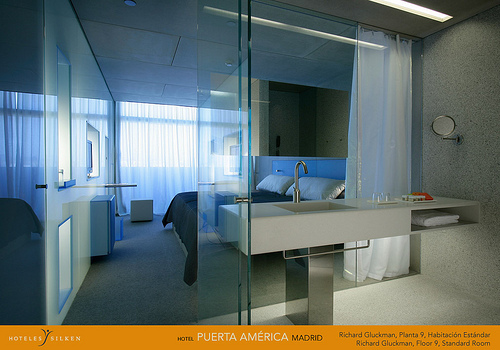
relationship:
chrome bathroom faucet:
[278, 151, 322, 218] [256, 159, 341, 262]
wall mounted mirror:
[447, 50, 480, 78] [418, 87, 482, 179]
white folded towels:
[417, 201, 478, 249] [431, 199, 465, 228]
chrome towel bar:
[278, 151, 322, 218] [266, 235, 374, 273]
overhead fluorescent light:
[376, 11, 465, 47] [375, 7, 460, 31]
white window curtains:
[417, 201, 478, 249] [106, 94, 178, 174]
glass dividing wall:
[208, 16, 261, 70] [447, 50, 480, 78]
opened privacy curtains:
[246, 26, 399, 230] [106, 94, 178, 174]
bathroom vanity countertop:
[273, 205, 374, 266] [369, 200, 392, 214]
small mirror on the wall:
[422, 112, 470, 126] [452, 109, 475, 179]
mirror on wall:
[418, 87, 482, 179] [447, 50, 480, 78]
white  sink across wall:
[244, 181, 369, 214] [447, 50, 480, 78]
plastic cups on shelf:
[53, 162, 71, 192] [55, 169, 77, 201]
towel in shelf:
[396, 207, 461, 239] [55, 169, 77, 201]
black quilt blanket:
[173, 194, 193, 222] [165, 180, 291, 233]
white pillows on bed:
[284, 165, 346, 213] [178, 153, 332, 250]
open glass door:
[137, 20, 240, 233] [162, 8, 256, 265]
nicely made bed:
[124, 160, 345, 270] [178, 153, 332, 250]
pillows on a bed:
[247, 161, 296, 206] [178, 153, 332, 250]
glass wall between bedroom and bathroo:
[2, 33, 413, 135] [136, 41, 447, 200]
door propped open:
[197, 0, 244, 325] [137, 20, 240, 233]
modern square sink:
[29, 33, 418, 254] [266, 193, 352, 223]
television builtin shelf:
[85, 135, 97, 177] [55, 169, 77, 201]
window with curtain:
[136, 108, 190, 190] [136, 127, 178, 150]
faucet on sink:
[256, 159, 341, 262] [266, 193, 352, 223]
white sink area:
[417, 201, 478, 249] [275, 151, 355, 233]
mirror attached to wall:
[418, 87, 482, 179] [447, 50, 480, 78]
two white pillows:
[242, 146, 350, 204] [247, 161, 296, 206]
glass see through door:
[208, 16, 261, 70] [162, 8, 256, 265]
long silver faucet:
[288, 156, 313, 211] [256, 159, 341, 262]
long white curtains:
[288, 156, 313, 211] [106, 94, 178, 174]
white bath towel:
[417, 201, 478, 249] [396, 207, 461, 239]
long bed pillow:
[288, 156, 313, 211] [253, 161, 347, 219]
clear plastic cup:
[53, 162, 71, 192] [21, 153, 83, 201]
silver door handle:
[216, 185, 261, 226] [24, 169, 54, 215]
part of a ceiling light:
[334, 7, 431, 51] [287, 4, 479, 36]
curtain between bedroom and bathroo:
[335, 25, 420, 278] [136, 41, 447, 200]